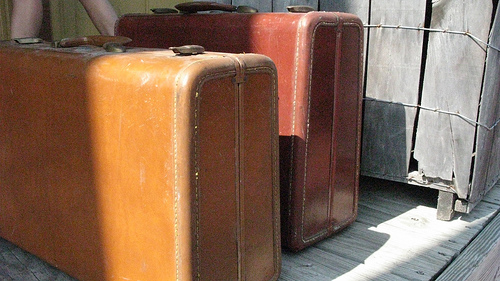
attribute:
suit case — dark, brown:
[115, 2, 367, 253]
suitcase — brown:
[287, 19, 370, 208]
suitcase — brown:
[8, 53, 194, 257]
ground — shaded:
[381, 132, 456, 200]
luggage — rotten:
[226, 0, 433, 234]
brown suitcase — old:
[1, 40, 281, 279]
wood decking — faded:
[337, 220, 435, 278]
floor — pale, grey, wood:
[2, 228, 79, 279]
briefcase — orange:
[5, 34, 284, 277]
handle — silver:
[45, 31, 132, 57]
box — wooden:
[367, 2, 497, 227]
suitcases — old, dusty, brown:
[2, 0, 367, 280]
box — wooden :
[368, 13, 493, 233]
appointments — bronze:
[185, 87, 207, 191]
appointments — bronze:
[296, 108, 316, 140]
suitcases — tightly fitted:
[15, 10, 400, 279]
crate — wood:
[370, 5, 497, 228]